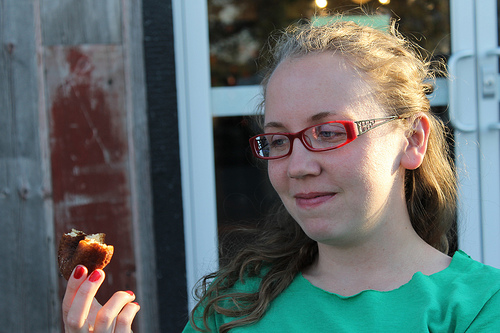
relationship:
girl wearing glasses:
[61, 22, 500, 332] [248, 115, 404, 160]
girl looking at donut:
[61, 22, 500, 332] [57, 228, 115, 282]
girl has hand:
[61, 22, 500, 332] [60, 265, 142, 333]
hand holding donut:
[60, 265, 142, 333] [57, 228, 115, 282]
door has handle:
[173, 0, 500, 333] [484, 47, 500, 134]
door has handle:
[173, 0, 500, 333] [445, 48, 477, 134]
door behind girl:
[173, 0, 500, 333] [61, 22, 500, 332]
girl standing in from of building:
[61, 22, 500, 332] [0, 1, 500, 333]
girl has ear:
[61, 22, 500, 332] [401, 112, 430, 170]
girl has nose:
[61, 22, 500, 332] [287, 140, 323, 180]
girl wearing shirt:
[61, 22, 500, 332] [182, 247, 499, 333]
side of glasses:
[356, 116, 406, 137] [248, 115, 404, 160]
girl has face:
[61, 22, 500, 332] [262, 50, 409, 240]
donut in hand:
[57, 228, 115, 282] [60, 265, 142, 333]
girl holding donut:
[61, 22, 500, 332] [57, 228, 115, 282]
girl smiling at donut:
[61, 22, 500, 332] [57, 228, 115, 282]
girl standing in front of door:
[61, 22, 500, 332] [173, 0, 500, 333]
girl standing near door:
[61, 22, 500, 332] [173, 0, 500, 333]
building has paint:
[0, 1, 500, 333] [40, 43, 138, 333]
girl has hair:
[61, 22, 500, 332] [183, 2, 466, 331]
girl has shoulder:
[61, 22, 500, 332] [207, 261, 313, 293]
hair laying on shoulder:
[183, 2, 466, 331] [207, 261, 313, 293]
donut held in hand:
[57, 228, 115, 282] [60, 265, 142, 333]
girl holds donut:
[61, 22, 500, 332] [57, 228, 115, 282]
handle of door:
[484, 47, 500, 134] [173, 0, 500, 333]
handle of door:
[445, 48, 477, 134] [173, 0, 500, 333]